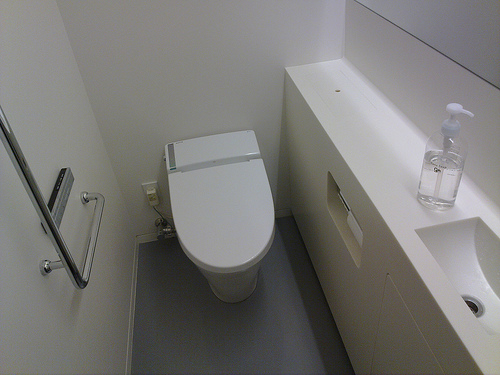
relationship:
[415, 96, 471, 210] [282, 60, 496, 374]
bottle of soap on top of counter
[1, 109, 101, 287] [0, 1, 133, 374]
chrome bar on side of wall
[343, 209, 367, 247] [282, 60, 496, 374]
toilet roll inside counter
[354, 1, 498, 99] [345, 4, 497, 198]
line in middle of wall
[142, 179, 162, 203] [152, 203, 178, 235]
outlet has wire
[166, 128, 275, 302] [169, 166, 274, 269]
toilet has toilet seat lid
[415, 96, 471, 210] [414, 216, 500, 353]
bottle of soap by sink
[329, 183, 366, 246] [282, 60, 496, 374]
toilet paper holder inside counter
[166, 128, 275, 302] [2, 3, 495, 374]
toilet inside bathroom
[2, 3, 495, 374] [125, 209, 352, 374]
bathroom has floor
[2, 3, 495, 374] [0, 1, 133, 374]
bathroom has wall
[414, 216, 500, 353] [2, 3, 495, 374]
sink inside bathroom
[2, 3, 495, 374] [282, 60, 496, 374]
bathroom has counter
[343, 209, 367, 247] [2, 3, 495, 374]
toilet roll inside bathroom